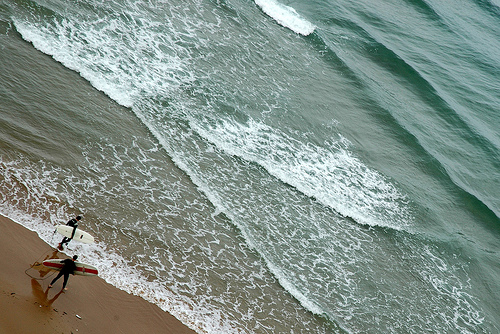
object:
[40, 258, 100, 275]
surfboard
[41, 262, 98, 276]
stripe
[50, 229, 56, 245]
tether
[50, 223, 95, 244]
board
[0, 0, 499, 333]
ripple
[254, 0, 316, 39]
foam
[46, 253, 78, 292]
person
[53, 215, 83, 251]
person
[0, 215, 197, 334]
area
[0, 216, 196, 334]
sand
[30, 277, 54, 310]
reflection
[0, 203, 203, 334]
beach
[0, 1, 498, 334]
tides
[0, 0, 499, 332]
sea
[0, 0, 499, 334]
photo